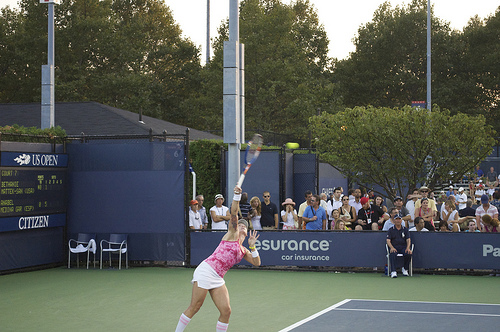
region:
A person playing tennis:
[120, 126, 358, 326]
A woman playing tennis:
[171, 117, 316, 325]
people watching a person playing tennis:
[196, 175, 387, 240]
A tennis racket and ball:
[229, 109, 318, 200]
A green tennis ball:
[278, 114, 338, 178]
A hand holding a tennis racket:
[220, 130, 265, 211]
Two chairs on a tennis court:
[54, 221, 146, 281]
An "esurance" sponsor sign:
[230, 224, 370, 282]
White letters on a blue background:
[251, 226, 351, 267]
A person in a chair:
[371, 207, 422, 287]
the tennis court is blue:
[334, 283, 434, 330]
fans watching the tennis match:
[277, 181, 482, 237]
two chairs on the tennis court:
[54, 218, 150, 270]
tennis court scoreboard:
[0, 164, 86, 220]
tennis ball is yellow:
[257, 128, 314, 161]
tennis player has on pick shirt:
[200, 165, 287, 294]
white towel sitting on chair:
[72, 240, 89, 263]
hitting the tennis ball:
[227, 114, 317, 199]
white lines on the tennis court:
[274, 286, 487, 321]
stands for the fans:
[441, 150, 498, 200]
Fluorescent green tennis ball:
[282, 127, 314, 165]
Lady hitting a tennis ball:
[155, 120, 296, 330]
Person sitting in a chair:
[378, 212, 422, 282]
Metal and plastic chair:
[92, 226, 135, 280]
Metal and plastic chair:
[54, 226, 104, 275]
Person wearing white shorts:
[161, 128, 285, 330]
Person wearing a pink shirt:
[160, 129, 280, 330]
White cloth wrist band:
[247, 242, 260, 262]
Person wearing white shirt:
[202, 184, 239, 235]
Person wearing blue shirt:
[295, 189, 332, 239]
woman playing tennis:
[188, 111, 302, 329]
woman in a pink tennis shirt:
[215, 206, 249, 303]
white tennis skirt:
[186, 233, 231, 304]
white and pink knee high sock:
[162, 313, 209, 329]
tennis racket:
[244, 123, 270, 205]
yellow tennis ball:
[285, 139, 310, 169]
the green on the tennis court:
[292, 272, 352, 302]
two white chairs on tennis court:
[53, 234, 157, 269]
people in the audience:
[245, 175, 498, 240]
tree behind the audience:
[289, 111, 499, 207]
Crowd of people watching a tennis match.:
[138, 123, 499, 262]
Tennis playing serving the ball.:
[197, 128, 309, 330]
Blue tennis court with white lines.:
[273, 277, 499, 327]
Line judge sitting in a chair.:
[381, 212, 419, 275]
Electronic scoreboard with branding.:
[1, 134, 81, 234]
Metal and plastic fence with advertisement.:
[187, 227, 499, 266]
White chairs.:
[61, 231, 132, 272]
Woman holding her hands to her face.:
[278, 195, 303, 246]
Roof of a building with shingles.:
[0, 96, 230, 153]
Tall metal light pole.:
[209, 2, 254, 201]